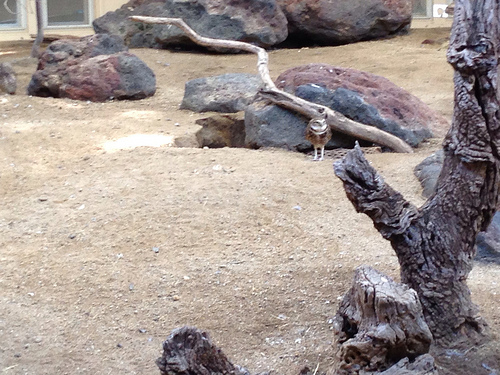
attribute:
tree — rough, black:
[420, 19, 498, 210]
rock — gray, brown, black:
[80, 40, 148, 106]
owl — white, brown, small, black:
[294, 113, 338, 164]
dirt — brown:
[64, 110, 155, 225]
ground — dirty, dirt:
[158, 181, 342, 270]